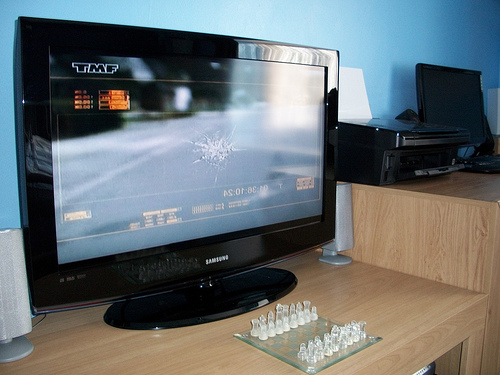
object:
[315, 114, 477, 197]
stereo system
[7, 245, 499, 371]
table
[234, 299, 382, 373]
chess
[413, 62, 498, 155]
computer monitor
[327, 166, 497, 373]
desk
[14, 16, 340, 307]
monitor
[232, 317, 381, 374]
glass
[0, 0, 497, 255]
wall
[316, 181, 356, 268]
speaker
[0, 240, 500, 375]
desk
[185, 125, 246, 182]
cracked glass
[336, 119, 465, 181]
computer printer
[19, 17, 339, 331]
tv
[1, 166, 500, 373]
desk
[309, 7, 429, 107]
blue walls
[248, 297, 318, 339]
pieces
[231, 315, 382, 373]
board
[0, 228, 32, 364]
gray speaker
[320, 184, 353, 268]
speaker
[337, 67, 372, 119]
paper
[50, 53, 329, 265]
computer monitor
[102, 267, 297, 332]
tv stand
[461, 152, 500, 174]
computer keyboard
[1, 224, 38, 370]
silver speaker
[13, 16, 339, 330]
computer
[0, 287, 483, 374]
table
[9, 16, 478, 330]
computer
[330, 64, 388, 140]
paper